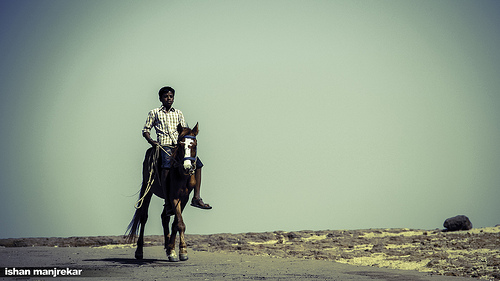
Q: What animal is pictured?
A: A horse.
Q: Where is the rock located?
A: On the right.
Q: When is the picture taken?
A: Daytime.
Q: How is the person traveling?
A: On horseback.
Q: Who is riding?
A: A man.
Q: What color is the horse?
A: Brown.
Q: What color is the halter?
A: Blue.